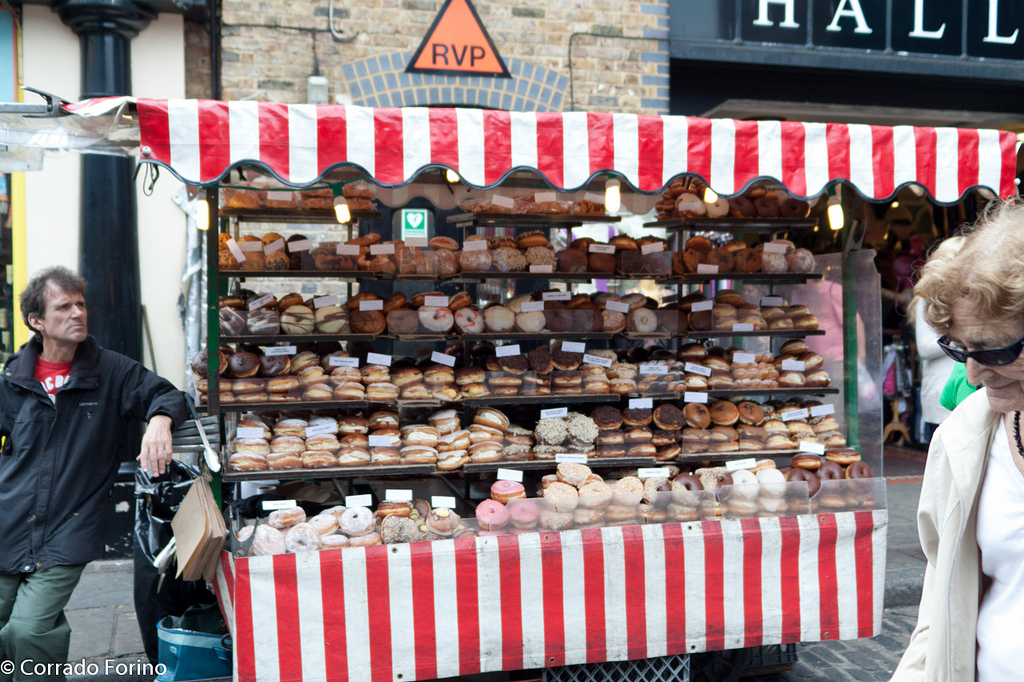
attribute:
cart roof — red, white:
[54, 92, 1018, 199]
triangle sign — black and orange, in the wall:
[397, 1, 514, 79]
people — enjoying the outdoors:
[889, 219, 1023, 678]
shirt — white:
[985, 512, 992, 573]